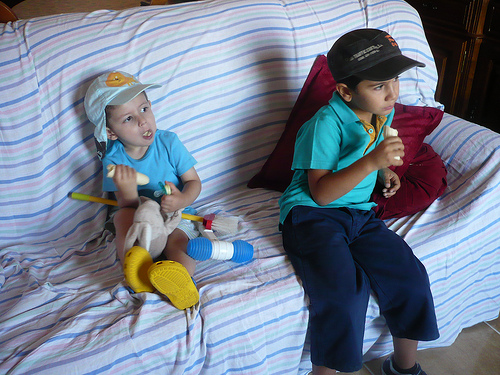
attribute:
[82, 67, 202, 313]
child — sitting, looking left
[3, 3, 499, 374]
couch — covered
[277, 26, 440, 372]
child — leaning, sitting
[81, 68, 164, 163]
hat — white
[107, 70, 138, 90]
goldfish — yellow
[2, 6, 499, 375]
blanket — striped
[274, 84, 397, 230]
shirt — teal, collared, blue, green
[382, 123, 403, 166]
banana — half eaten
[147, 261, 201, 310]
shoe — rubber, yellow, croc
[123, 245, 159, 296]
shoe — rubber, yellow, croc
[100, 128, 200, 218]
shirt — teal, blue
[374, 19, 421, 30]
stripe — blue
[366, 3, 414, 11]
stripe — pink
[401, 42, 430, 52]
stripe — white, blue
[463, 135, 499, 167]
stripe — grey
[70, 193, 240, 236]
toy broom — yellow red, white, yellow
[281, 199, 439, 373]
pants — dark blue, navy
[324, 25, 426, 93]
hat — black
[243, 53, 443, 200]
pillow — red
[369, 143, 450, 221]
pillow — red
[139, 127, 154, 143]
mouth — open, full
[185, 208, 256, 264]
toy — blue, white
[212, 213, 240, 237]
bristles — white